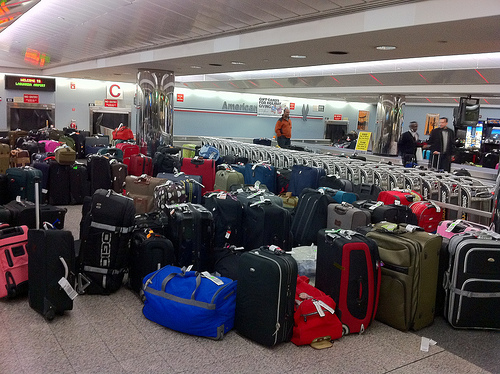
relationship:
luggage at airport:
[137, 260, 241, 342] [1, 2, 499, 374]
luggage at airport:
[363, 220, 443, 334] [1, 2, 499, 374]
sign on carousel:
[353, 130, 376, 158] [290, 134, 498, 188]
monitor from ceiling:
[450, 96, 486, 132] [1, 0, 499, 109]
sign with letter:
[353, 130, 376, 158] [109, 84, 121, 99]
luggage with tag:
[363, 220, 443, 334] [269, 240, 294, 258]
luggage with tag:
[137, 260, 241, 342] [199, 267, 225, 290]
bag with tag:
[284, 271, 345, 353] [312, 296, 337, 319]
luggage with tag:
[363, 220, 443, 334] [129, 170, 150, 180]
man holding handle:
[424, 115, 457, 175] [429, 150, 442, 170]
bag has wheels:
[26, 224, 78, 320] [44, 309, 55, 322]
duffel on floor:
[139, 259, 241, 342] [2, 158, 500, 373]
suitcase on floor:
[364, 218, 445, 337] [2, 158, 500, 373]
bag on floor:
[284, 271, 345, 353] [2, 158, 500, 373]